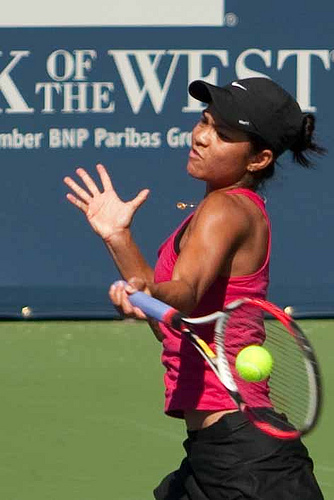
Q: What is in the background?
A: A blue banner.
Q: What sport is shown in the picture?
A: Tennis.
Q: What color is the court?
A: Green.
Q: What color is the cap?
A: Black.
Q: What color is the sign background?
A: Blue.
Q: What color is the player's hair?
A: Black.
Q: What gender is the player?
A: Female.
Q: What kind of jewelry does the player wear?
A: Necklace.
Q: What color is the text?
A: White.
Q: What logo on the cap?
A: Nike.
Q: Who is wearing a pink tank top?
A: A young, female tennis player.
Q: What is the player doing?
A: Returning the ball with a hit.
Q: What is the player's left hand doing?
A: Executing a left-handed forehand hit.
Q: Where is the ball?
A: In the center of the player's racket.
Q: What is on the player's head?
A: A black, Nike cap.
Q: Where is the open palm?
A: At the end of the player's right arm.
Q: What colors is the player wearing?
A: Pink and black.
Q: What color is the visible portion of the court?
A: Green.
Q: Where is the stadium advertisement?
A: At the far end of the court.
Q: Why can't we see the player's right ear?
A: The player is turned to the left.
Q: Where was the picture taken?
A: On a tennis court.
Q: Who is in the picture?
A: A woman.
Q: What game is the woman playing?
A: Tennis.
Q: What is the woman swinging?
A: A racket.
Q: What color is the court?
A: Green.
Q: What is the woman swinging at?
A: A ball.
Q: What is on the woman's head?
A: A hat.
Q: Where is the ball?
A: In the air.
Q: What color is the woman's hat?
A: Black.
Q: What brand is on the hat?
A: Nike.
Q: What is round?
A: Tennis ball.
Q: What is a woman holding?
A: Tennis racket.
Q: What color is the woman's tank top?
A: Pink.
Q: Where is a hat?
A: On woman's head.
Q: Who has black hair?
A: Tennis player.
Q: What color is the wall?
A: Blue.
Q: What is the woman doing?
A: Playing tennis.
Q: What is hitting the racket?
A: Tennis ball.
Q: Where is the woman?
A: On a tennis court.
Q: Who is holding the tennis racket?
A: The woman.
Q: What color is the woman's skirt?
A: Black.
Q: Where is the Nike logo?
A: On the hat.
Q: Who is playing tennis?
A: The woman.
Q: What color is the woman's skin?
A: Brown.